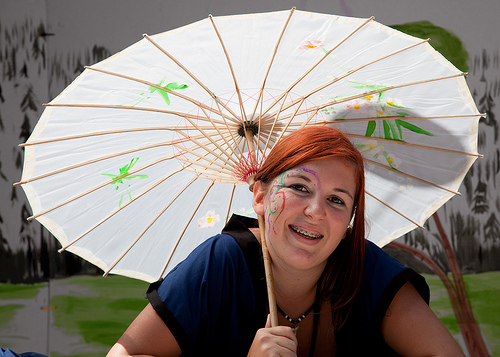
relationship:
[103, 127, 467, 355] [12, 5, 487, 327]
girl holding umbrella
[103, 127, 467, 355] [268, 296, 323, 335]
girl has necklace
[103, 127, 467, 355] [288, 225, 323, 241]
girl has braces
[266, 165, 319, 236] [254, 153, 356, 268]
paint on face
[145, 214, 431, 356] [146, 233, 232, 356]
shirt has sleeve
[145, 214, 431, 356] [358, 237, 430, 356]
shirt has sleeve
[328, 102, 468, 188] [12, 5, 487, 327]
shadow on umbrella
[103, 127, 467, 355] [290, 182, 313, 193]
girl has eye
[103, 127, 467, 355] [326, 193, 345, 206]
girl has eye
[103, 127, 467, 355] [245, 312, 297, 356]
girl has hand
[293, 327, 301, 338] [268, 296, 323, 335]
charm on necklace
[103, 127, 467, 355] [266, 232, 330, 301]
girl has neck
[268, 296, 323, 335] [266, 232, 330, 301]
necklace around neck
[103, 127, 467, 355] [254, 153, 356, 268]
girl has face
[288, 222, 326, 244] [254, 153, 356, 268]
mouth on face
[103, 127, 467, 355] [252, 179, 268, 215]
girl has ear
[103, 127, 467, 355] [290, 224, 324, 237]
girl has upper teeth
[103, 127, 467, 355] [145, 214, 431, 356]
girl wearing shirt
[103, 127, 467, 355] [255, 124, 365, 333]
girl has hair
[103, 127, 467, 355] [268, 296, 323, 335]
girl wearing necklace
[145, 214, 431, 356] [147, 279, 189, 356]
shirt has border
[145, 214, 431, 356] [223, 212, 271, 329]
shirt has border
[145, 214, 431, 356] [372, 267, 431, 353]
shirt has border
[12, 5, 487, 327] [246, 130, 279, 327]
umbrella has stick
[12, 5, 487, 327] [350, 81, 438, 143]
umbrella has flowers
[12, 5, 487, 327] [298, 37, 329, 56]
umbrella has flowers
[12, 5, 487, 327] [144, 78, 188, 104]
umbrella has flowers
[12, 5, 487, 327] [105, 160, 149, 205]
umbrella has flowers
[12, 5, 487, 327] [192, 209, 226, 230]
umbrella has flowers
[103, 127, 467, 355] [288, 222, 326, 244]
girl has mouth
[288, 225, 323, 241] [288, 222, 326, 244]
braces are in mouth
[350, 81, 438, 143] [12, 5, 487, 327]
flowers are on umbrella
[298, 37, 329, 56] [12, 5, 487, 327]
flowers are on umbrella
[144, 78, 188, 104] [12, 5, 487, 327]
flowers are on umbrella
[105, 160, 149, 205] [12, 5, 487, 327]
flowers are on umbrella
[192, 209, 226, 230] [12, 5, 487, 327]
flowers are on umbrella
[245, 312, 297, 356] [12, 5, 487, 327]
hand holding umbrella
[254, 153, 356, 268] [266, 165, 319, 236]
face has paint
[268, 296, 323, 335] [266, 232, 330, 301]
necklace on neck